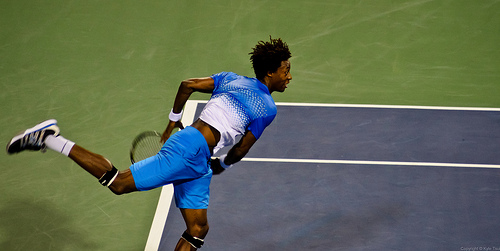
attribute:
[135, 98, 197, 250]
line — colored white, long, white in color, white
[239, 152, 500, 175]
line — white in color, a white color, colored white, white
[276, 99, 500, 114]
line — colored white, white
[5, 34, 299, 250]
tennis player — black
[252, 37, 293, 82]
hair — dark brown, dark, natural black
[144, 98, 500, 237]
tennis court — green, blue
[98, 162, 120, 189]
band — blank, white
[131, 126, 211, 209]
shorts — baby blue, blue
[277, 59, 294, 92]
face — brown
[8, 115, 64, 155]
shoe — black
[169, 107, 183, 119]
wristband — white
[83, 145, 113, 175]
leg muscle — bulging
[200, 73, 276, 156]
shirt — white, blue